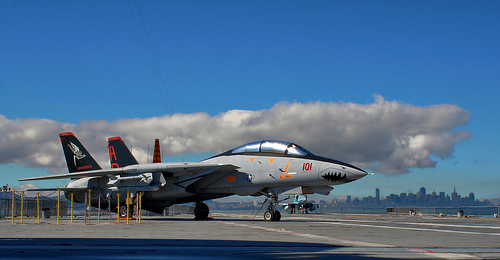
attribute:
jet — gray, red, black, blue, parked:
[16, 131, 378, 221]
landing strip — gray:
[0, 212, 498, 258]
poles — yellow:
[8, 188, 141, 227]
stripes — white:
[204, 211, 499, 251]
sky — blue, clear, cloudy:
[0, 2, 498, 202]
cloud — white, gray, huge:
[2, 93, 475, 177]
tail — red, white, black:
[56, 129, 140, 204]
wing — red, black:
[17, 160, 229, 183]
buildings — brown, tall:
[309, 186, 492, 209]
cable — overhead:
[129, 0, 194, 161]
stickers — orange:
[227, 157, 295, 181]